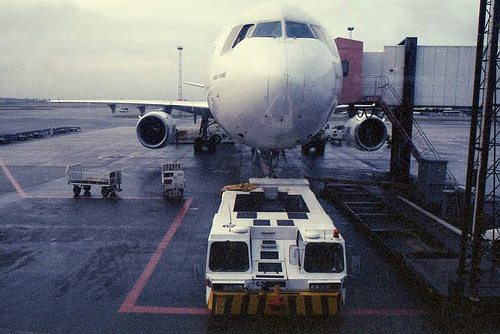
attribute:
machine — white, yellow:
[200, 174, 352, 319]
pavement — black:
[13, 103, 496, 332]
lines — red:
[8, 160, 433, 316]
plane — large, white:
[49, 7, 385, 177]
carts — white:
[60, 158, 189, 198]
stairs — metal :
[375, 74, 460, 184]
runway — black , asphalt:
[2, 103, 176, 324]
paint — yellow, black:
[204, 287, 342, 317]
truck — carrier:
[200, 172, 350, 326]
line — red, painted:
[2, 158, 454, 318]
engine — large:
[134, 111, 180, 144]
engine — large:
[348, 116, 387, 151]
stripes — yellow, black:
[212, 291, 341, 315]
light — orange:
[331, 226, 340, 240]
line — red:
[116, 193, 208, 319]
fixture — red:
[267, 285, 288, 311]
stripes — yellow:
[206, 284, 343, 319]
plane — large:
[68, 24, 399, 199]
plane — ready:
[83, 24, 403, 234]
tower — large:
[167, 35, 209, 109]